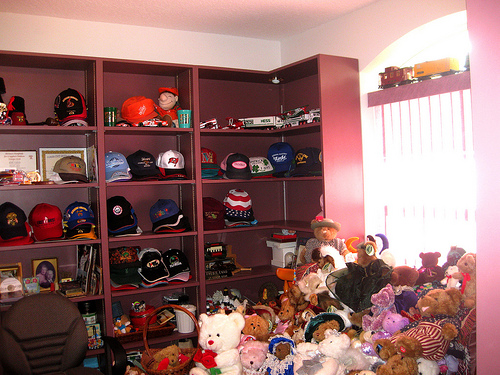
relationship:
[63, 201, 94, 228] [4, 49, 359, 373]
hat on shelf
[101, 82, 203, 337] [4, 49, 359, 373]
ball caps on shelf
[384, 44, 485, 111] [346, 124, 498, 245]
train above window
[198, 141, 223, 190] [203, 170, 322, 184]
cap on shelf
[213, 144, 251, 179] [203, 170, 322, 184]
cap on shelf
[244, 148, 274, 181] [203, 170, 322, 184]
cap on shelf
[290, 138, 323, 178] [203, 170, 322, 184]
cap on shelf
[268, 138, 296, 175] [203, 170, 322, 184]
cap on shelf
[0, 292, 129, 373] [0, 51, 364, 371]
chair in front of shelves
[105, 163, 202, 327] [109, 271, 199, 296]
ball caps on shelf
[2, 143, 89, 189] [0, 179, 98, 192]
certificates on shelf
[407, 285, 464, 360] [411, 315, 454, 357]
bear wearing clothing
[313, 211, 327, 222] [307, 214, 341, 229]
flower on hat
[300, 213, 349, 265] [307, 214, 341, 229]
teddy bear wearing hat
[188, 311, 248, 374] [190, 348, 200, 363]
bear holding flower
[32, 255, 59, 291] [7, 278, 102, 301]
photo on shelf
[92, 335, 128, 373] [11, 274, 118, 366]
armrest on chair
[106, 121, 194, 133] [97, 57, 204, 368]
shelf on bookcase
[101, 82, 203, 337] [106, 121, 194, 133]
ball caps on shelf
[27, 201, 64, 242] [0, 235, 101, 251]
red hat on shelf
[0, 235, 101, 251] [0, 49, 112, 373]
shelf on bookcase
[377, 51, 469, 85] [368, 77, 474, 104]
train on shelf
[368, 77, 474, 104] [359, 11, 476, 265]
shelf above window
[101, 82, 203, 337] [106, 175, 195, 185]
ball caps on shelf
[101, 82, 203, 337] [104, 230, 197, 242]
ball caps on shelf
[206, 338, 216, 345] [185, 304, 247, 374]
nose on bear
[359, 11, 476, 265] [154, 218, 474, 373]
window behind stuffed animals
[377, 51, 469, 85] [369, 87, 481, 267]
train above window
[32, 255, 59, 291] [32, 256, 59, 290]
photo in frame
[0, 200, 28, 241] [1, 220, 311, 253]
cap on shelf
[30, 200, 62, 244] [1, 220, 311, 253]
cap on shelf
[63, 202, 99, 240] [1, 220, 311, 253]
cap on shelf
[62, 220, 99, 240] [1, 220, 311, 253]
cap on shelf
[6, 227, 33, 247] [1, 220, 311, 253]
cap on shelf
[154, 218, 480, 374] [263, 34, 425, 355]
stuffed animals in corner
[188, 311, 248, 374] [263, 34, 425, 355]
bear in corner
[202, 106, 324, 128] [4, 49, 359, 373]
toys on shelf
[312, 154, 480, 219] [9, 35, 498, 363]
sunlight streaming into room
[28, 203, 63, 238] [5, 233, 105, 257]
hat on shelf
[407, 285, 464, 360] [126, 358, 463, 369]
bear on floor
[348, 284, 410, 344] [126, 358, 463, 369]
teddy bears on floor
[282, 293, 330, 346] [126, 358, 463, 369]
teddy bears on floor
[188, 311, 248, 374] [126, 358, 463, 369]
bear on floor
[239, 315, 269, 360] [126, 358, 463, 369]
teddy bears on floor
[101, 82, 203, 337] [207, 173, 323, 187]
ball caps on shelf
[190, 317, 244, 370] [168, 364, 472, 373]
bear on floor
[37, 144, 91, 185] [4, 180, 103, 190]
certificate behind shelf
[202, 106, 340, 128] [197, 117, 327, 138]
toys on shelf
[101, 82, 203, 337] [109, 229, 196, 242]
ball caps on shelf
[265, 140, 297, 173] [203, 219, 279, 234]
hat on shelf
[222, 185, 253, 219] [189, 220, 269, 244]
hat on shelf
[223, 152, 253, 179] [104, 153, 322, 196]
hat on shelf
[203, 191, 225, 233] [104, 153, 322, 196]
hat on shelf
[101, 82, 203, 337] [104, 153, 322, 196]
ball caps on shelf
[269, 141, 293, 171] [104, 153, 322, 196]
hat on shelf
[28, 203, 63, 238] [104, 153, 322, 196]
hat on shelf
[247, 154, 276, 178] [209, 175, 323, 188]
hat on shelf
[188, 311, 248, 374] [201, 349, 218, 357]
bear holding flower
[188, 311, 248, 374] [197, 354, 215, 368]
bear holding flower